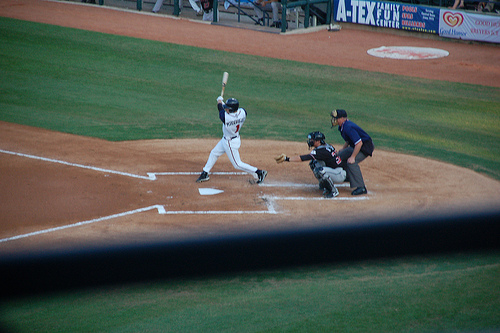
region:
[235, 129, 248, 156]
part of a jersey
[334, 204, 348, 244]
part of a shoe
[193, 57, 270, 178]
A batter hitting a ball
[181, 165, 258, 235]
home plate without dust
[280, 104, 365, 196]
A catcher catching a ball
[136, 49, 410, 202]
A player swinging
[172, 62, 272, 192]
A player swinging at a pitch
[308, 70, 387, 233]
An umpire watching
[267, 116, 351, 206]
A catcher ready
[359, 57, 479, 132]
A nice baseball field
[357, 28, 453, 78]
No one warming up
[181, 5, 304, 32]
Players watching from dugout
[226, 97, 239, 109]
blue plastic batting helmet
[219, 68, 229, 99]
natural wood baseball bat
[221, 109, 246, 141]
white and red jersey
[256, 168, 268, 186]
black and grey cleat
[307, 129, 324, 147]
black plastic catchers mask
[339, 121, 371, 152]
blue cotton polo shirt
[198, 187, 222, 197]
white rubber home plate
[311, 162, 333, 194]
grey pads on knees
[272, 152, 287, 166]
brown leather catchers mitt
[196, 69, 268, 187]
man swinging baseball bat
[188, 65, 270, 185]
Baseball player swinging the bat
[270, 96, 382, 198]
Umpire standing behind the catcher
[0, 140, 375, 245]
White lines are on the dirt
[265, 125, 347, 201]
The catcher is crouched down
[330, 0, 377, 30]
"A-TEX" written on a sign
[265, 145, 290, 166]
A brown leather glove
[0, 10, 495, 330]
Green grass on the field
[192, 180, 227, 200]
Home plate is white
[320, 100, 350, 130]
Umpire wearing a face mask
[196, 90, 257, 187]
Batter wearing a white uniform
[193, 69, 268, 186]
batter is swinging a baseball bat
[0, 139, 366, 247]
white markings on a baseball field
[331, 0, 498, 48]
advertising around a baseball field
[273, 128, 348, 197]
catcher is crouched down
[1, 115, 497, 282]
red dirt on a baseball field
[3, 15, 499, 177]
green grass on a baseball field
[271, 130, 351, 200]
catcher wears a leather glove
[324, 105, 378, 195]
umpire is leaning forward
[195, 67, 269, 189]
batter wears a white uniform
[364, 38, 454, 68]
a white circle in red dirt